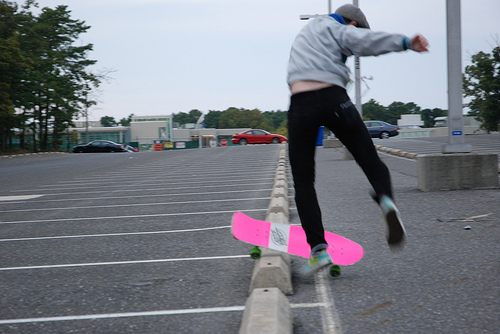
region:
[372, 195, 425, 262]
this is a shoe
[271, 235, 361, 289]
a white small shoe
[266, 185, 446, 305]
these are the shoes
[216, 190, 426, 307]
this is a skateboard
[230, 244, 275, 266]
this is a wheel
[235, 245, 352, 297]
these are the wheels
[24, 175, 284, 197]
this is a parking spot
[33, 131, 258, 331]
these are the parking spots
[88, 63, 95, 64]
this is a leaf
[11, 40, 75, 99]
these are the leaves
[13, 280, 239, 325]
White line on the pavement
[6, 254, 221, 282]
White line on the pavement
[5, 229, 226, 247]
White line on the pavement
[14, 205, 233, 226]
White line on the pavement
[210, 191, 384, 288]
Pink an white skateboard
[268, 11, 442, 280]
Man wearing black pants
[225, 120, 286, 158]
Car parked on the pavement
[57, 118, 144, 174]
Car parked on the pavement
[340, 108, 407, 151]
Car parked on the pavement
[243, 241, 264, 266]
Green wheel of a skateboard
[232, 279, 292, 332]
Concrete boarder on the pavement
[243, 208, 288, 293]
Concrete boarder on the pavement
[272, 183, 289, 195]
Concrete boarder on the pavement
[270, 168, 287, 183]
Concrete boarder on the pavement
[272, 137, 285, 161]
Concrete boarder on the pavement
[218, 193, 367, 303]
Pink and white skateboard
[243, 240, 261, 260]
Green wherl on a skateborad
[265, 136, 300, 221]
Row of curbs in a parking lot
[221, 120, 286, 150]
Small red car in a parking lot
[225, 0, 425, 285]
Boy riding a skateboard in a parking lot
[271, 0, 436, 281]
Boy in a gray hoodie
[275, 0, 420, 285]
Boy wearing black skinny jeans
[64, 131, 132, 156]
Blue car in the back of the parking lot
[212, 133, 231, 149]
Red stop sign at the edge of the parking lot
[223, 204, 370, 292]
Pink and white skateboard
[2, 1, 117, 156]
Large tree in the corner of a parking lot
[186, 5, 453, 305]
Skater falling off of his skateboard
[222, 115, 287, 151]
Red car parked in the parking lot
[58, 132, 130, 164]
dark colored car in the parking lot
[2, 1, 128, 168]
Tall trees on the corner of the parking lot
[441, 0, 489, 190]
Large concrete pole in the middle of the parking lot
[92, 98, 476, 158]
line of trees on the horizon in the distance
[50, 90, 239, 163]
Large building seen in the background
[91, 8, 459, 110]
Overcast sky above the empty parking lot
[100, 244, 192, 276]
Line in a parking lot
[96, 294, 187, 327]
Line in a parking lot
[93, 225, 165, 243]
Line in a parking lot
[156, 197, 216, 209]
Line in a parking lot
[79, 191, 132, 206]
Line in a parking lot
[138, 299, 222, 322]
Line in a parking lot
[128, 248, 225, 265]
Line in a parking lot